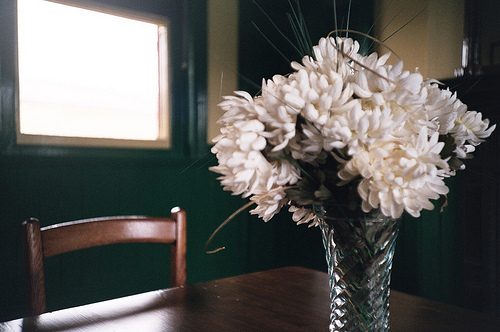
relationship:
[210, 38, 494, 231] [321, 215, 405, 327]
flower inside vase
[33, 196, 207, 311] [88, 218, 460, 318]
chair under edge of table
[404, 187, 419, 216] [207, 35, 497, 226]
petals forming flower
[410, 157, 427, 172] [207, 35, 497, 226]
petals forming flower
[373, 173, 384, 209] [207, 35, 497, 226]
petals forming flower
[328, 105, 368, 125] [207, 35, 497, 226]
petals forming flower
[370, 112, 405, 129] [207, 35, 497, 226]
petals forming flower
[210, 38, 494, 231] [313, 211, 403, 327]
flower in a glass vase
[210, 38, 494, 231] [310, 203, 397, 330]
flower in a vase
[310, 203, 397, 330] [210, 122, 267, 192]
vase has flower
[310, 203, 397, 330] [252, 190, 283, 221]
vase has flower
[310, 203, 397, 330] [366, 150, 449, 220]
vase has flower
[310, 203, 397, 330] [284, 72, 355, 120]
vase has flower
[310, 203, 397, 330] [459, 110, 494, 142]
vase has flower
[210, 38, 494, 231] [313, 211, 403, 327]
flower in vase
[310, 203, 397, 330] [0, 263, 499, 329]
vase on table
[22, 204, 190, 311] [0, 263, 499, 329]
chair near table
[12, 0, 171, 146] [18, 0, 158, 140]
frame on window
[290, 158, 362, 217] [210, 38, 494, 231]
stems on flower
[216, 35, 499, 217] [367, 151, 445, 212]
bouquet of flower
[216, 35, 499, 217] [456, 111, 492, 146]
bouquet of flower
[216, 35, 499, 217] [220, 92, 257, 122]
bouquet of flower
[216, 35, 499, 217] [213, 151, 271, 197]
bouquet of flower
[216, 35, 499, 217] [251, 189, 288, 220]
bouquet of flower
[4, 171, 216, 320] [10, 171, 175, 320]
wall behind chair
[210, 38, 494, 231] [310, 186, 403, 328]
flower in a vase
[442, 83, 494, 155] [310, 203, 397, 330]
flower in a vase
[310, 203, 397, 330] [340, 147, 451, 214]
vase has flowers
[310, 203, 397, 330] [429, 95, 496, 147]
vase has flowers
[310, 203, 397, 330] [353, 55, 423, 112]
vase has flowers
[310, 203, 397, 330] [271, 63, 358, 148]
vase has flowers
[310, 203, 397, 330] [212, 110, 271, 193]
vase has flowers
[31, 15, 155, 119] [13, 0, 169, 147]
daylight thru window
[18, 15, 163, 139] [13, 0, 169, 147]
daylight thru window